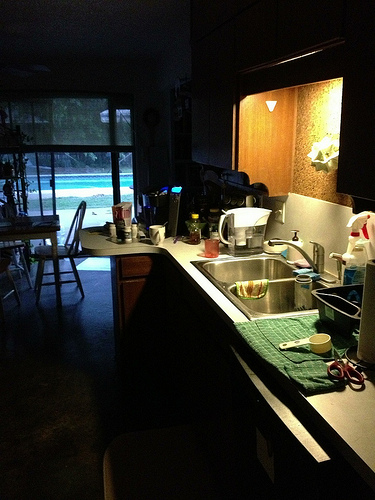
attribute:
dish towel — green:
[234, 315, 355, 395]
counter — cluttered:
[81, 218, 372, 472]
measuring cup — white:
[279, 335, 330, 354]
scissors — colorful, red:
[330, 346, 363, 386]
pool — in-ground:
[1, 173, 127, 199]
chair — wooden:
[34, 202, 87, 304]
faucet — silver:
[264, 239, 325, 273]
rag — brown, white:
[237, 281, 269, 300]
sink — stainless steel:
[193, 259, 324, 318]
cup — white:
[148, 225, 167, 244]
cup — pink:
[204, 240, 220, 256]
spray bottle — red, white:
[344, 211, 371, 270]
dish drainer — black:
[314, 282, 366, 331]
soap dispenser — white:
[285, 231, 304, 265]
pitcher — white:
[216, 208, 274, 255]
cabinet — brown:
[188, 90, 297, 198]